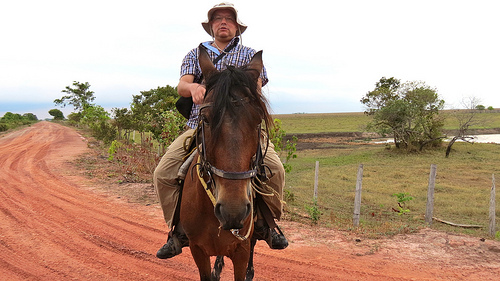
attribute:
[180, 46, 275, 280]
horse — brown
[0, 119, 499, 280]
dirt — red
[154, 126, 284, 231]
pants — khaki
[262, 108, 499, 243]
grass — green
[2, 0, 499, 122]
sky — white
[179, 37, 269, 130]
shirt — plaid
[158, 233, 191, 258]
shoe — dark brown